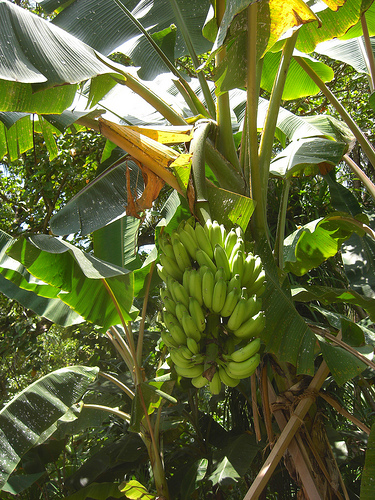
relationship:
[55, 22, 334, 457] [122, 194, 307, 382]
banana tree in forest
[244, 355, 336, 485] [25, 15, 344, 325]
wood on a tree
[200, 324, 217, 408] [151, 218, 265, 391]
stem on banana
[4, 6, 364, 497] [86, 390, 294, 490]
tree of bananas in a field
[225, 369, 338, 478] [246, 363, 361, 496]
planks holding up a banana trunk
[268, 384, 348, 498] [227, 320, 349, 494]
rope tied to planks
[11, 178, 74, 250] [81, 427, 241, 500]
twigs in background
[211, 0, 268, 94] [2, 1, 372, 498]
leaf on a banana tree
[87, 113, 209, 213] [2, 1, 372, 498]
leaf on a banana tree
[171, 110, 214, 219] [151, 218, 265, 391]
branch being pulled down by weight of banana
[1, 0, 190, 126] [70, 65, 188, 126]
leaf reflecting sunlight